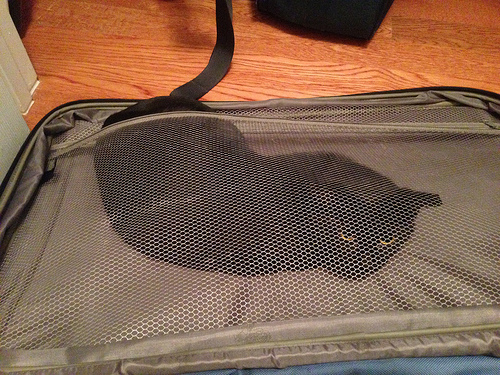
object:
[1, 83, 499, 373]
bag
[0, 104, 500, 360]
flap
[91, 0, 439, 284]
cat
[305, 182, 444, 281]
head